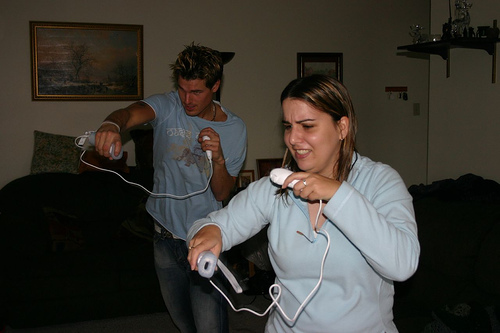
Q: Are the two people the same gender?
A: No, they are both male and female.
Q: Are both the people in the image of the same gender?
A: No, they are both male and female.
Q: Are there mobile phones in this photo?
A: No, there are no mobile phones.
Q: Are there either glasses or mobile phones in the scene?
A: No, there are no mobile phones or glasses.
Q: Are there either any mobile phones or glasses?
A: No, there are no mobile phones or glasses.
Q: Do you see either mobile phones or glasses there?
A: No, there are no mobile phones or glasses.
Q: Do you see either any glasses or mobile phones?
A: No, there are no mobile phones or glasses.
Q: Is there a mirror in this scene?
A: No, there are no mirrors.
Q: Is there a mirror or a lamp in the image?
A: No, there are no mirrors or lamps.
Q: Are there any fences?
A: No, there are no fences.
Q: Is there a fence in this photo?
A: No, there are no fences.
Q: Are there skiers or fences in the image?
A: No, there are no fences or skiers.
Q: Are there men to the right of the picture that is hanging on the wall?
A: Yes, there is a man to the right of the picture.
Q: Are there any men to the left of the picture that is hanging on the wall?
A: No, the man is to the right of the picture.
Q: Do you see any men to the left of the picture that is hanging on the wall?
A: No, the man is to the right of the picture.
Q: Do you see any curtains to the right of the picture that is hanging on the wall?
A: No, there is a man to the right of the picture.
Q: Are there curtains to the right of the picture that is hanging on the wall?
A: No, there is a man to the right of the picture.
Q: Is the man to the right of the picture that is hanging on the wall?
A: Yes, the man is to the right of the picture.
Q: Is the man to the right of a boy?
A: No, the man is to the right of the picture.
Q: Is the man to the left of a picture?
A: No, the man is to the right of a picture.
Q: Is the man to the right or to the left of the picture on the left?
A: The man is to the right of the picture.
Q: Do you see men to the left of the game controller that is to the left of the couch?
A: Yes, there is a man to the left of the game controller.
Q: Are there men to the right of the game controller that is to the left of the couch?
A: No, the man is to the left of the game controller.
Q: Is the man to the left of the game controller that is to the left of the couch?
A: Yes, the man is to the left of the game controller.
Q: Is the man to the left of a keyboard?
A: No, the man is to the left of the game controller.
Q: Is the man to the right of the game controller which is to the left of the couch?
A: No, the man is to the left of the game controller.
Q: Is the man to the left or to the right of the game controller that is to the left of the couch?
A: The man is to the left of the game controller.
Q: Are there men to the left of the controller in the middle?
A: Yes, there is a man to the left of the controller.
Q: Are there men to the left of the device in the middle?
A: Yes, there is a man to the left of the controller.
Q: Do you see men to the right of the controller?
A: No, the man is to the left of the controller.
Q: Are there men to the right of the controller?
A: No, the man is to the left of the controller.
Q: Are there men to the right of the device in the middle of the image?
A: No, the man is to the left of the controller.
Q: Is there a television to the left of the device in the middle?
A: No, there is a man to the left of the controller.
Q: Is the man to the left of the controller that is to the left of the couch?
A: Yes, the man is to the left of the controller.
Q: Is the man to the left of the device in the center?
A: Yes, the man is to the left of the controller.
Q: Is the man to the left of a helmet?
A: No, the man is to the left of the controller.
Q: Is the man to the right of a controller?
A: No, the man is to the left of a controller.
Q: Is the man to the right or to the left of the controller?
A: The man is to the left of the controller.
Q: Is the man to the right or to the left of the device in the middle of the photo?
A: The man is to the left of the controller.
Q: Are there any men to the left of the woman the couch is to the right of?
A: Yes, there is a man to the left of the woman.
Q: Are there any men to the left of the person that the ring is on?
A: Yes, there is a man to the left of the woman.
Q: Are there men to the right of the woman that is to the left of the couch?
A: No, the man is to the left of the woman.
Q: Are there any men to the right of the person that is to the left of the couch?
A: No, the man is to the left of the woman.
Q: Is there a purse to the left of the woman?
A: No, there is a man to the left of the woman.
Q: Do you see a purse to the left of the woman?
A: No, there is a man to the left of the woman.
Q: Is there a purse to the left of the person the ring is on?
A: No, there is a man to the left of the woman.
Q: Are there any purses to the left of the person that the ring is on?
A: No, there is a man to the left of the woman.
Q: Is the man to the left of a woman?
A: Yes, the man is to the left of a woman.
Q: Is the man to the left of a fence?
A: No, the man is to the left of a woman.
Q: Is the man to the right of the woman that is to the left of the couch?
A: No, the man is to the left of the woman.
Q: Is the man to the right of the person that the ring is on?
A: No, the man is to the left of the woman.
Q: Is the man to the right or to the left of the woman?
A: The man is to the left of the woman.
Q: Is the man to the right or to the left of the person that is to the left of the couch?
A: The man is to the left of the woman.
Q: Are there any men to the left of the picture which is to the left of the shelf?
A: Yes, there is a man to the left of the picture.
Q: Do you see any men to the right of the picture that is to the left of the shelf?
A: No, the man is to the left of the picture.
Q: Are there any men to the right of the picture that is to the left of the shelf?
A: No, the man is to the left of the picture.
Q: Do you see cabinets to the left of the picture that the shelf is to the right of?
A: No, there is a man to the left of the picture.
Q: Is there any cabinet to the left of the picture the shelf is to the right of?
A: No, there is a man to the left of the picture.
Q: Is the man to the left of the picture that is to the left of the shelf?
A: Yes, the man is to the left of the picture.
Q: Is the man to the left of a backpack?
A: No, the man is to the left of the picture.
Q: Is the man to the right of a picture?
A: No, the man is to the left of a picture.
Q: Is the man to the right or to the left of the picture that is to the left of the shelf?
A: The man is to the left of the picture.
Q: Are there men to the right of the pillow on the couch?
A: Yes, there is a man to the right of the pillow.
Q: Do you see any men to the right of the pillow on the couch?
A: Yes, there is a man to the right of the pillow.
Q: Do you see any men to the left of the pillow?
A: No, the man is to the right of the pillow.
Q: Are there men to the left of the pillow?
A: No, the man is to the right of the pillow.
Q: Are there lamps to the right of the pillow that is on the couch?
A: No, there is a man to the right of the pillow.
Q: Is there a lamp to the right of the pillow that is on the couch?
A: No, there is a man to the right of the pillow.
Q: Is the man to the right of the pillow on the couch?
A: Yes, the man is to the right of the pillow.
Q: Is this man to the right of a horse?
A: No, the man is to the right of the pillow.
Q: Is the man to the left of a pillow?
A: No, the man is to the right of a pillow.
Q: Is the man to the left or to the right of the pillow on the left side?
A: The man is to the right of the pillow.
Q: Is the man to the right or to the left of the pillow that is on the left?
A: The man is to the right of the pillow.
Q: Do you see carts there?
A: No, there are no carts.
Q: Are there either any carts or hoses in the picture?
A: No, there are no carts or hoses.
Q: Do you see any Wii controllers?
A: Yes, there is a Wii controller.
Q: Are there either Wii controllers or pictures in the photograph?
A: Yes, there is a Wii controller.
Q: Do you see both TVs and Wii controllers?
A: No, there is a Wii controller but no televisions.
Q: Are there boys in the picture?
A: No, there are no boys.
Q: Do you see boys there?
A: No, there are no boys.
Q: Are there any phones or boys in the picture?
A: No, there are no boys or phones.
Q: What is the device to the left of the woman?
A: The device is a Wii controller.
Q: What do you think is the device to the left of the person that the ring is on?
A: The device is a Wii controller.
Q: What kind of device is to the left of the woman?
A: The device is a Wii controller.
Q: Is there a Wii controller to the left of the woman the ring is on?
A: Yes, there is a Wii controller to the left of the woman.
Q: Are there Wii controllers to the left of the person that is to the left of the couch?
A: Yes, there is a Wii controller to the left of the woman.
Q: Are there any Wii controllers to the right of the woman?
A: No, the Wii controller is to the left of the woman.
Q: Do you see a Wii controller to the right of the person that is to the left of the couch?
A: No, the Wii controller is to the left of the woman.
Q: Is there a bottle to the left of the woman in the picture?
A: No, there is a Wii controller to the left of the woman.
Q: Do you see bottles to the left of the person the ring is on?
A: No, there is a Wii controller to the left of the woman.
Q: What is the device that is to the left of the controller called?
A: The device is a Wii controller.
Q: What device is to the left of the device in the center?
A: The device is a Wii controller.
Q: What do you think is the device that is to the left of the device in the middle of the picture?
A: The device is a Wii controller.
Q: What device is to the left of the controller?
A: The device is a Wii controller.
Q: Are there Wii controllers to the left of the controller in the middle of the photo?
A: Yes, there is a Wii controller to the left of the controller.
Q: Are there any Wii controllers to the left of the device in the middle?
A: Yes, there is a Wii controller to the left of the controller.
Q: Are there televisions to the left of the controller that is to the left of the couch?
A: No, there is a Wii controller to the left of the controller.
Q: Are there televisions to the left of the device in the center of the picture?
A: No, there is a Wii controller to the left of the controller.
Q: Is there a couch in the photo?
A: Yes, there is a couch.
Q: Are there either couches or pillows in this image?
A: Yes, there is a couch.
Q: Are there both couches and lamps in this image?
A: No, there is a couch but no lamps.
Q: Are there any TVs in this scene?
A: No, there are no tvs.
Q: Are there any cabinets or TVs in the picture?
A: No, there are no TVs or cabinets.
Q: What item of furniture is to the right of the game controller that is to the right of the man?
A: The piece of furniture is a couch.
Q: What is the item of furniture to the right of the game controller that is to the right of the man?
A: The piece of furniture is a couch.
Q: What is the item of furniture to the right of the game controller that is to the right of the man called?
A: The piece of furniture is a couch.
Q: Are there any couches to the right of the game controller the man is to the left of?
A: Yes, there is a couch to the right of the game controller.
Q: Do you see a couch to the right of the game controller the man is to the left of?
A: Yes, there is a couch to the right of the game controller.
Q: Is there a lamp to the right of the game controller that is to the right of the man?
A: No, there is a couch to the right of the game controller.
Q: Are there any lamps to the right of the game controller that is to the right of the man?
A: No, there is a couch to the right of the game controller.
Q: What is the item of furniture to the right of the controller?
A: The piece of furniture is a couch.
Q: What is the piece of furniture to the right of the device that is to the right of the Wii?
A: The piece of furniture is a couch.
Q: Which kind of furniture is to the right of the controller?
A: The piece of furniture is a couch.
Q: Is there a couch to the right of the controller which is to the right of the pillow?
A: Yes, there is a couch to the right of the controller.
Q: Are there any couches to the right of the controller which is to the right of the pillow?
A: Yes, there is a couch to the right of the controller.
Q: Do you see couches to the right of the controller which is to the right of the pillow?
A: Yes, there is a couch to the right of the controller.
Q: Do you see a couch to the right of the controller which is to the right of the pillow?
A: Yes, there is a couch to the right of the controller.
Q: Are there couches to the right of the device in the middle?
A: Yes, there is a couch to the right of the controller.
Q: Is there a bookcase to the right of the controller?
A: No, there is a couch to the right of the controller.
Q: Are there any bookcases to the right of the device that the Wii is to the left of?
A: No, there is a couch to the right of the controller.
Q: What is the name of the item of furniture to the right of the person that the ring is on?
A: The piece of furniture is a couch.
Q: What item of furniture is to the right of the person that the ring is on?
A: The piece of furniture is a couch.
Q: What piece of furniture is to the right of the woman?
A: The piece of furniture is a couch.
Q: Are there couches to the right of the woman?
A: Yes, there is a couch to the right of the woman.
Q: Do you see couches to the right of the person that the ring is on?
A: Yes, there is a couch to the right of the woman.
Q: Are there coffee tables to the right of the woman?
A: No, there is a couch to the right of the woman.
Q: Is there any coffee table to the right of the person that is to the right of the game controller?
A: No, there is a couch to the right of the woman.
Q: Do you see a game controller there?
A: Yes, there is a game controller.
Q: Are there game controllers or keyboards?
A: Yes, there is a game controller.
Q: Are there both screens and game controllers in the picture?
A: No, there is a game controller but no screens.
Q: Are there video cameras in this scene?
A: No, there are no video cameras.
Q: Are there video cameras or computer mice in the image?
A: No, there are no video cameras or computer mice.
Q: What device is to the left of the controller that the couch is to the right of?
A: The device is a game controller.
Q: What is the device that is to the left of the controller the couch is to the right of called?
A: The device is a game controller.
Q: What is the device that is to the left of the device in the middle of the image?
A: The device is a game controller.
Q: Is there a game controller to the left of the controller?
A: Yes, there is a game controller to the left of the controller.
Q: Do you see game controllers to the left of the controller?
A: Yes, there is a game controller to the left of the controller.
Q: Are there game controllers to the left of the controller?
A: Yes, there is a game controller to the left of the controller.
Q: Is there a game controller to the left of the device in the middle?
A: Yes, there is a game controller to the left of the controller.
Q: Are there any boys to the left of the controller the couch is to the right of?
A: No, there is a game controller to the left of the controller.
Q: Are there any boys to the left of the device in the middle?
A: No, there is a game controller to the left of the controller.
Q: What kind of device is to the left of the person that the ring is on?
A: The device is a game controller.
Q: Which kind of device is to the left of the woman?
A: The device is a game controller.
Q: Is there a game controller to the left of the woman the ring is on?
A: Yes, there is a game controller to the left of the woman.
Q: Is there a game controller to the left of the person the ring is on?
A: Yes, there is a game controller to the left of the woman.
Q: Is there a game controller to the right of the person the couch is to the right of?
A: No, the game controller is to the left of the woman.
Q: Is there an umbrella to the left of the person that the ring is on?
A: No, there is a game controller to the left of the woman.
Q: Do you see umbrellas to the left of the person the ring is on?
A: No, there is a game controller to the left of the woman.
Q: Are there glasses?
A: No, there are no glasses.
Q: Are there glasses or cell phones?
A: No, there are no glasses or cell phones.